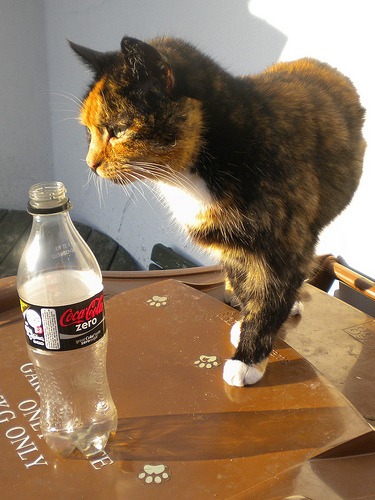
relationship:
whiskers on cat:
[117, 169, 164, 224] [64, 55, 357, 363]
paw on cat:
[221, 356, 269, 389] [67, 32, 369, 391]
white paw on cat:
[291, 298, 304, 315] [67, 32, 369, 391]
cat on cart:
[71, 47, 336, 238] [23, 267, 372, 500]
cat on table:
[67, 32, 369, 391] [4, 273, 361, 495]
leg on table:
[222, 250, 298, 387] [4, 273, 361, 495]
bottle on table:
[17, 167, 133, 462] [4, 273, 361, 495]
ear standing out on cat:
[66, 39, 106, 74] [67, 32, 369, 391]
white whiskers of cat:
[81, 172, 94, 189] [67, 32, 369, 391]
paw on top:
[218, 356, 273, 388] [2, 248, 370, 497]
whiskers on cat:
[117, 160, 201, 225] [88, 52, 355, 301]